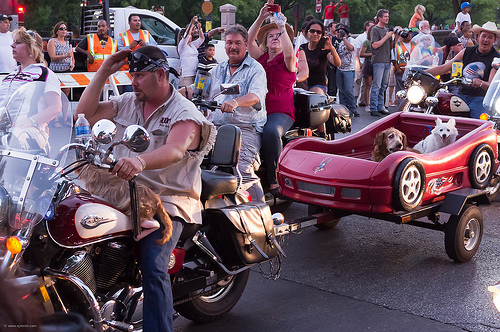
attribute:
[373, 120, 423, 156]
dog — brown, white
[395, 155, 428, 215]
wheel — black, white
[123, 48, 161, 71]
glasses — dark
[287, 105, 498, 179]
car — small, red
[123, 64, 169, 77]
bandana — black, white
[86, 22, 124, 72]
vest — orange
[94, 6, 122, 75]
man — brown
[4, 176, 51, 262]
headlamp — shining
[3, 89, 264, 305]
motorcycle — red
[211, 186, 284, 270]
bag — black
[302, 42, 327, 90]
t-shirt — black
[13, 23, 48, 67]
female — blonde